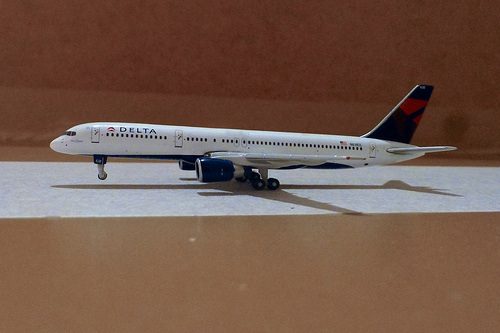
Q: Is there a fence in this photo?
A: No, there are no fences.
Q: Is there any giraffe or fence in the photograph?
A: No, there are no fences or giraffes.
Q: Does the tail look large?
A: Yes, the tail is large.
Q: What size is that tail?
A: The tail is large.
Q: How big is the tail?
A: The tail is large.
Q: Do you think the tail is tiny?
A: No, the tail is large.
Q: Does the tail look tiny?
A: No, the tail is large.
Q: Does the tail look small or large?
A: The tail is large.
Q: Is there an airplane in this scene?
A: Yes, there are airplanes.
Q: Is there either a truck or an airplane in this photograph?
A: Yes, there are airplanes.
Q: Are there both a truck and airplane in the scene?
A: No, there are airplanes but no trucks.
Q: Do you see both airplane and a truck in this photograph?
A: No, there are airplanes but no trucks.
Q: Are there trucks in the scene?
A: No, there are no trucks.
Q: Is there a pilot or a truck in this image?
A: No, there are no trucks or pilots.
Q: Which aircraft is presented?
A: The aircraft is airplanes.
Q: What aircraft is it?
A: The aircraft is airplanes.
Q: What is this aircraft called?
A: These are airplanes.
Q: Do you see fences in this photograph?
A: No, there are no fences.